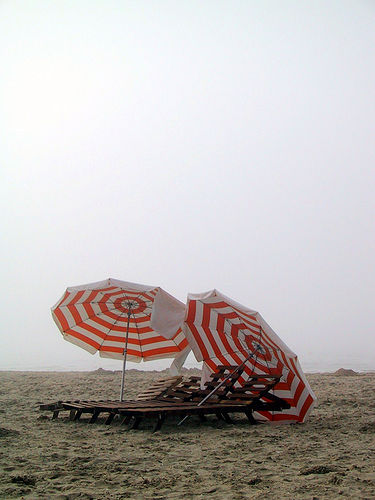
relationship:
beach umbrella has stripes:
[50, 278, 192, 422] [63, 323, 105, 347]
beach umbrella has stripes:
[177, 287, 318, 428] [63, 323, 105, 347]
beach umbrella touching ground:
[177, 287, 318, 428] [7, 380, 372, 498]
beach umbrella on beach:
[50, 278, 192, 422] [1, 371, 374, 497]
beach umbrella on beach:
[177, 287, 318, 428] [1, 371, 374, 497]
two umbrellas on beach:
[49, 277, 316, 424] [3, 362, 374, 488]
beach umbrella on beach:
[50, 278, 192, 422] [25, 372, 149, 392]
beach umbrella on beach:
[177, 287, 318, 428] [25, 372, 149, 392]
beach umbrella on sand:
[50, 278, 192, 422] [24, 434, 357, 490]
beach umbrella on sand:
[177, 287, 318, 428] [0, 368, 374, 498]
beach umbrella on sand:
[50, 278, 192, 422] [0, 368, 374, 498]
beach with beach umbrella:
[0, 366, 374, 499] [50, 278, 192, 422]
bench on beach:
[119, 373, 292, 435] [6, 356, 370, 497]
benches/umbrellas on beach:
[40, 375, 185, 423] [1, 371, 374, 497]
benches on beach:
[61, 376, 203, 425] [1, 371, 374, 497]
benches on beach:
[91, 366, 245, 432] [1, 371, 374, 497]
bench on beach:
[119, 373, 292, 435] [1, 371, 374, 497]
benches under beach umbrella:
[87, 395, 212, 420] [50, 278, 192, 422]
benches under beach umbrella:
[87, 395, 212, 420] [177, 287, 318, 428]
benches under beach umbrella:
[39, 366, 288, 428] [177, 287, 318, 428]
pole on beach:
[120, 311, 133, 402] [10, 378, 359, 493]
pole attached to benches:
[120, 311, 133, 402] [91, 366, 245, 432]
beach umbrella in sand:
[177, 287, 318, 428] [47, 419, 307, 478]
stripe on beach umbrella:
[62, 324, 101, 350] [50, 278, 192, 422]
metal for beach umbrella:
[88, 286, 156, 328] [50, 278, 192, 422]